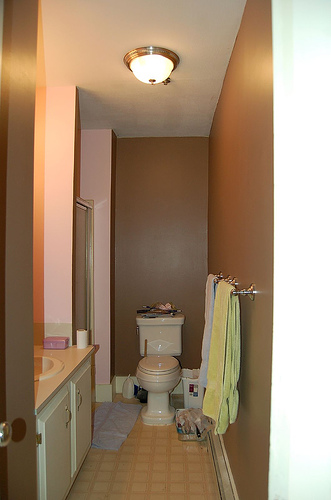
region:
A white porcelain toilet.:
[136, 316, 184, 424]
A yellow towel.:
[200, 278, 239, 433]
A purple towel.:
[199, 276, 214, 388]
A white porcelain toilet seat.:
[139, 349, 181, 375]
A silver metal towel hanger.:
[205, 271, 259, 301]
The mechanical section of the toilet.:
[134, 313, 183, 355]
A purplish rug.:
[93, 400, 142, 450]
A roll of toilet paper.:
[74, 328, 89, 350]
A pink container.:
[40, 337, 68, 349]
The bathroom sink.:
[34, 344, 94, 499]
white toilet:
[132, 273, 190, 435]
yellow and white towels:
[195, 315, 248, 434]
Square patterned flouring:
[115, 454, 164, 497]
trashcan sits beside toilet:
[177, 350, 220, 419]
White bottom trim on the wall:
[96, 351, 157, 408]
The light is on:
[115, 39, 208, 82]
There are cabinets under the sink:
[20, 344, 81, 487]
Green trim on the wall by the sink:
[38, 309, 80, 394]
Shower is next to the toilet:
[54, 188, 123, 392]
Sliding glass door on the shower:
[65, 179, 143, 406]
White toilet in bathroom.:
[134, 312, 185, 425]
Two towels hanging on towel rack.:
[201, 273, 240, 435]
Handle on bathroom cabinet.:
[75, 388, 83, 411]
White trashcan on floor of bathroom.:
[182, 367, 205, 413]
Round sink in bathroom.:
[31, 354, 62, 380]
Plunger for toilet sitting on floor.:
[138, 339, 149, 402]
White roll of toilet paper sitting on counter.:
[76, 327, 89, 350]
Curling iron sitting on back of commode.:
[135, 304, 183, 314]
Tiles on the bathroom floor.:
[135, 457, 165, 485]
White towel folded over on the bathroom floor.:
[90, 399, 142, 449]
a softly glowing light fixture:
[117, 42, 184, 90]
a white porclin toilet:
[130, 315, 185, 438]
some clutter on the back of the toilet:
[134, 294, 183, 326]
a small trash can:
[179, 365, 208, 416]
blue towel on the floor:
[85, 398, 140, 449]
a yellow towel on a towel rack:
[203, 265, 245, 444]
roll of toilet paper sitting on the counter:
[73, 325, 97, 356]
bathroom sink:
[24, 347, 64, 393]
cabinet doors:
[39, 359, 110, 498]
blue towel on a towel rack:
[196, 268, 224, 409]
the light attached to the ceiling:
[122, 48, 173, 85]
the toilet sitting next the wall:
[134, 315, 182, 427]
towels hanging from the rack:
[201, 273, 244, 435]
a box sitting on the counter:
[43, 331, 69, 350]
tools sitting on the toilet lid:
[138, 302, 183, 321]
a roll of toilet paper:
[74, 329, 89, 349]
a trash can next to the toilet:
[180, 367, 203, 409]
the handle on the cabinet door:
[62, 404, 72, 427]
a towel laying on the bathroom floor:
[98, 400, 134, 452]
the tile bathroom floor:
[100, 424, 207, 498]